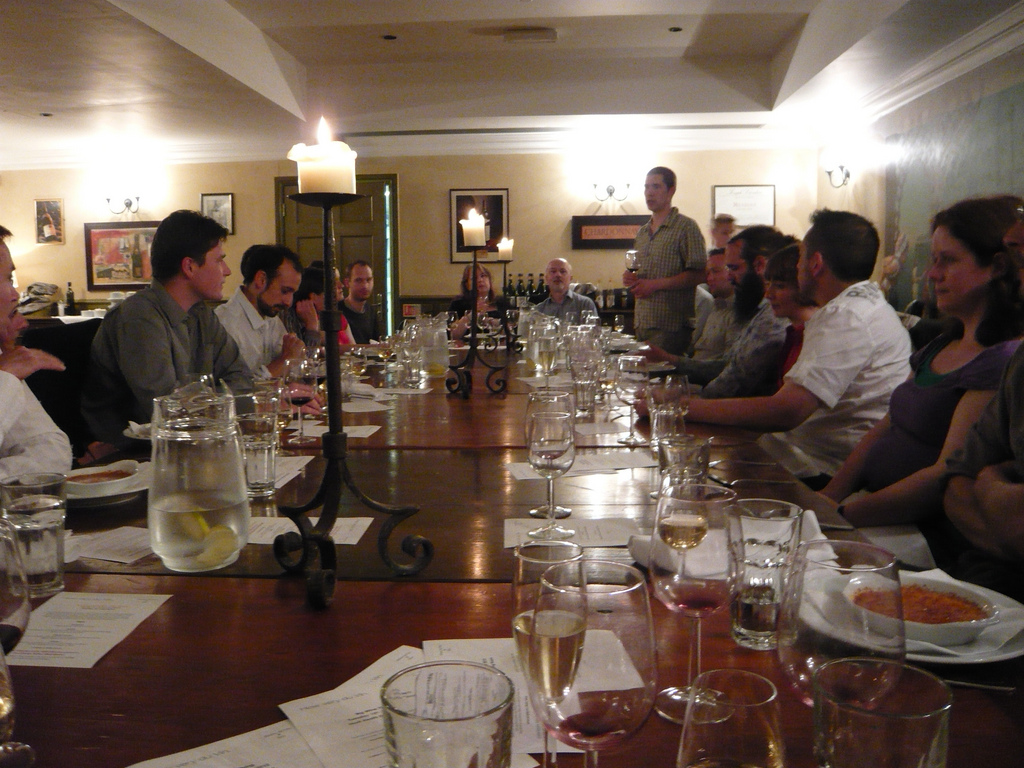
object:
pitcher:
[147, 379, 249, 573]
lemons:
[159, 502, 239, 568]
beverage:
[624, 249, 641, 289]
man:
[633, 206, 915, 492]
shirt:
[755, 280, 916, 477]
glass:
[526, 411, 576, 541]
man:
[87, 209, 323, 428]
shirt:
[83, 276, 256, 415]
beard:
[729, 267, 764, 332]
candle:
[287, 113, 358, 195]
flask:
[147, 388, 251, 574]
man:
[622, 165, 709, 356]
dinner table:
[0, 340, 1024, 768]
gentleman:
[536, 258, 599, 328]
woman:
[811, 194, 1024, 528]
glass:
[655, 466, 709, 595]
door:
[276, 174, 400, 343]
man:
[632, 224, 786, 398]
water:
[147, 490, 249, 572]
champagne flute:
[514, 540, 590, 768]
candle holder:
[276, 193, 437, 609]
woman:
[447, 263, 510, 340]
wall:
[0, 110, 901, 299]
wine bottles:
[503, 273, 546, 310]